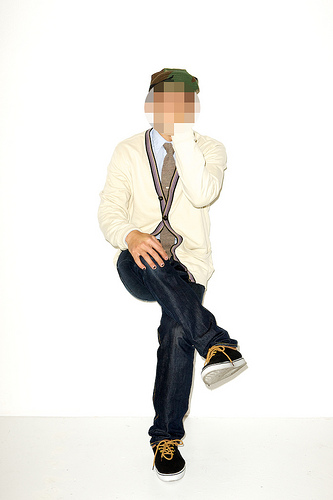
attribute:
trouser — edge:
[115, 248, 239, 439]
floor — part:
[0, 412, 328, 498]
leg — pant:
[173, 288, 207, 326]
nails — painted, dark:
[136, 254, 175, 274]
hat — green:
[141, 64, 209, 93]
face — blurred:
[149, 76, 208, 139]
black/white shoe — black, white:
[148, 438, 187, 481]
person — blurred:
[90, 39, 236, 322]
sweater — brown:
[94, 122, 234, 285]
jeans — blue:
[111, 244, 241, 450]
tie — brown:
[154, 141, 195, 278]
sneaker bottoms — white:
[204, 362, 251, 392]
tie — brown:
[152, 141, 203, 190]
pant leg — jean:
[147, 313, 194, 440]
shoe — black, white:
[190, 338, 252, 386]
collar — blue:
[148, 128, 166, 155]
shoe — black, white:
[150, 436, 186, 483]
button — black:
[156, 194, 165, 200]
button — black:
[160, 213, 169, 222]